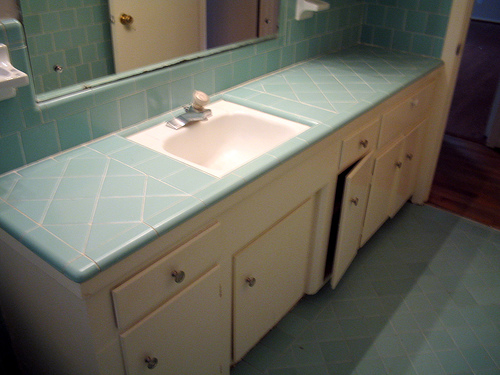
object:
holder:
[296, 3, 328, 22]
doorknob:
[119, 13, 135, 26]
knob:
[245, 276, 256, 288]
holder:
[1, 41, 30, 106]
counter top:
[4, 29, 444, 289]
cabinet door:
[321, 147, 374, 291]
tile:
[1, 1, 452, 173]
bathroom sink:
[152, 110, 297, 175]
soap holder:
[1, 40, 30, 102]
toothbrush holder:
[0, 41, 31, 100]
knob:
[350, 196, 359, 206]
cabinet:
[110, 264, 224, 372]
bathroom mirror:
[17, 2, 291, 103]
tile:
[411, 262, 433, 278]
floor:
[350, 265, 495, 372]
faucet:
[166, 90, 211, 130]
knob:
[169, 263, 190, 283]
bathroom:
[0, 0, 488, 365]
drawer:
[111, 221, 221, 327]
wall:
[0, 5, 448, 155]